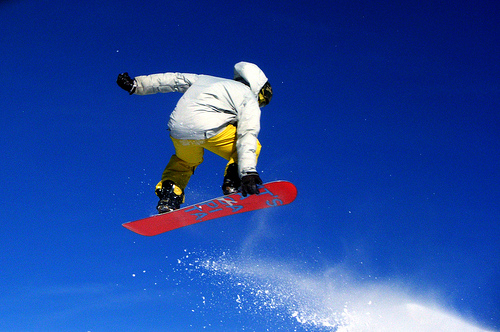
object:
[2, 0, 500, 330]
sky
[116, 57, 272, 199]
person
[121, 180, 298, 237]
snowboard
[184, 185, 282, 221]
graphics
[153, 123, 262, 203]
pants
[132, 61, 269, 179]
jacket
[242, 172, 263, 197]
glove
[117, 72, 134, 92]
glove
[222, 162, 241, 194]
boot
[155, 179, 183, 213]
boot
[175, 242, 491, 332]
snow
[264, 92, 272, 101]
goggles